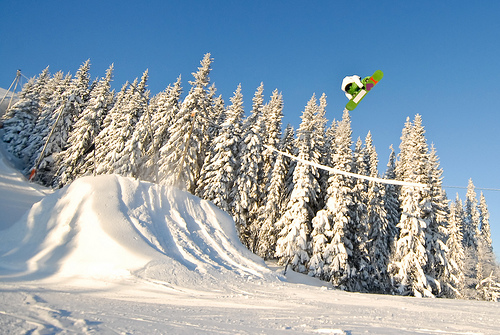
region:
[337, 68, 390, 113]
A person doing a flip on a snowboard.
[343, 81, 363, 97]
Skier wearing a green helmet.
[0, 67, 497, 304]
Snow covered pine trees.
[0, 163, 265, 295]
A ski ramp made of snow.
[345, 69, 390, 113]
A green snowboard.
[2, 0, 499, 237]
Cloudless blue sky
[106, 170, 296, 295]
Tracks of other snowboarders.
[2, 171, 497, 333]
Ground covered with snow.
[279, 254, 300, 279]
Trunk of a pine tree.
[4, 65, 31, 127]
Utility pole behind pine trees.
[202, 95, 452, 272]
the trees are snow covered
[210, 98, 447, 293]
the snow is white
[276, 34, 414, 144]
a snowboarder is in the air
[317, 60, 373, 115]
the person is wearing white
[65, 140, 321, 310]
a huge snow hill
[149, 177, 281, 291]
lines in the snow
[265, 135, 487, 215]
wire with snow on it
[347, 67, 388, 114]
bottom of the board is green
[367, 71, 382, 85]
the letter I is red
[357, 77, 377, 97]
a heart on the snowboard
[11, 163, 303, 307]
a big mound of snow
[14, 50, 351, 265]
snow covered pine trees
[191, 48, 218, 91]
the top of a snow covered tree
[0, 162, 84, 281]
the shadows of trees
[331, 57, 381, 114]
a snowboarder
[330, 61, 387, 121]
a snowboarder doing a trick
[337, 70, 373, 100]
a person high in the air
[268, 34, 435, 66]
a piece of blue sky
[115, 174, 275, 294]
indents in the snow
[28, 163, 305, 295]
a snow ramp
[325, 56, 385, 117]
snowboarder flying against blue sky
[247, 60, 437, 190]
curved white jumping line under snowboarder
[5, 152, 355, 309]
ramp formed of snow on slope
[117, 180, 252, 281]
deep impressions on the ramp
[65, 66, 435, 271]
tall and thin evergreens covered in snow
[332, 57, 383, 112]
green board with letter, heart and white space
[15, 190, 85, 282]
shadow of trees on side of ramp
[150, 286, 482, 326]
small pieces of snow strewn along surface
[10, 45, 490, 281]
poles along edge of trees supporting rope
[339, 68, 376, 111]
snowboarder in white jacket leaning over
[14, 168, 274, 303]
THIS IS A HILL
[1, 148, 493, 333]
THE SNOW IS BRIGHT WHITE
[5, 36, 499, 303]
THE SNOW IS COVERING THE TREES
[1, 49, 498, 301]
THE TREES ARE EVERGREENS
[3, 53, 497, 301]
THE TREES ARE SKINNY AND TALL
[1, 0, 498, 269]
THE SKY ABOVE THE TREES IS BLUE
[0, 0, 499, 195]
THE SKY ABOVE THE TREES IS CLEAR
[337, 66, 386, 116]
THE SNOWBOARDER IS IN THE AIR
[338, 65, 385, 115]
THE SNOWBOARDER IS DOING A TRICK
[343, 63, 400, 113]
THE SNOWBOARD IS GREEN